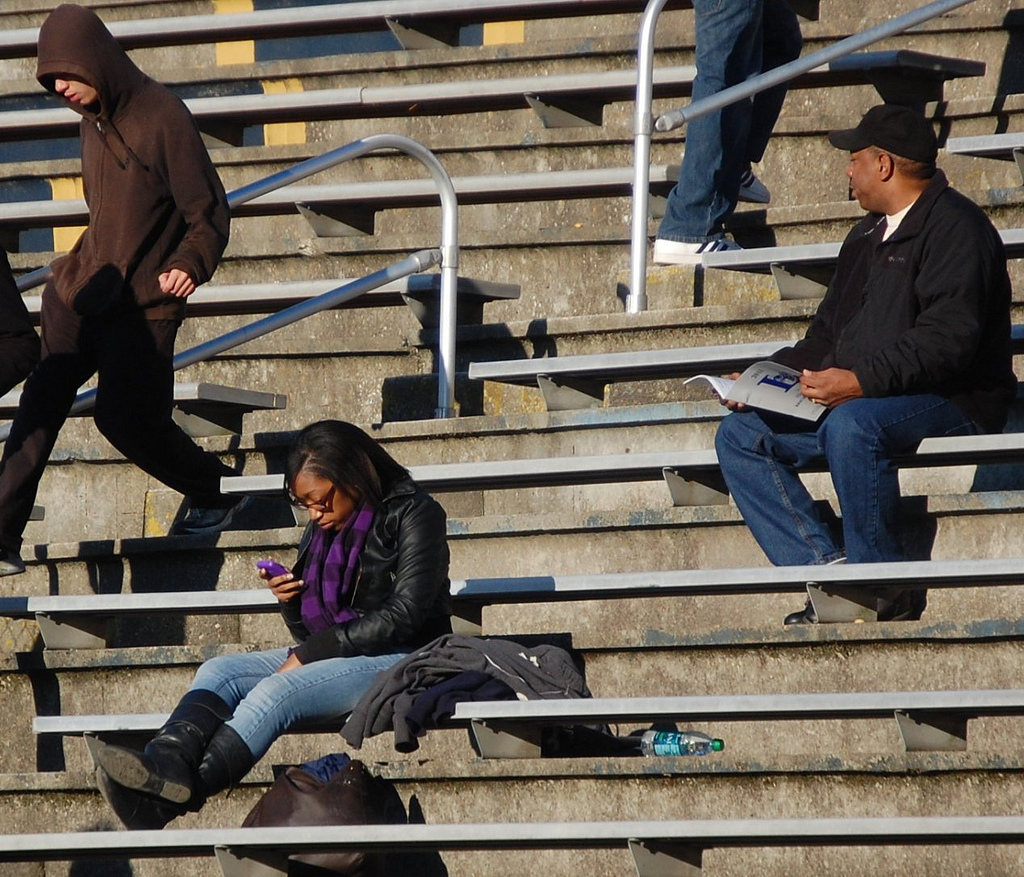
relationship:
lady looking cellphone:
[85, 418, 454, 813] [218, 494, 338, 641]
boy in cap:
[792, 92, 952, 346] [829, 104, 939, 165]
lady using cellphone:
[85, 418, 454, 813] [218, 494, 338, 641]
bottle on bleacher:
[641, 730, 726, 757] [686, 696, 730, 785]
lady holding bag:
[389, 588, 622, 783] [160, 371, 706, 814]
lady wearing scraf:
[85, 418, 454, 813] [278, 510, 351, 630]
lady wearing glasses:
[85, 418, 454, 813] [250, 452, 370, 519]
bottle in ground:
[542, 665, 754, 817] [667, 669, 738, 758]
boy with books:
[715, 103, 1014, 618] [599, 39, 963, 669]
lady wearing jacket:
[6, 14, 251, 368] [10, 103, 264, 294]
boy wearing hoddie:
[792, 92, 952, 346] [809, 184, 985, 371]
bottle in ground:
[542, 665, 754, 817] [611, 649, 649, 698]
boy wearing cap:
[715, 103, 1014, 618] [829, 104, 939, 165]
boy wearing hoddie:
[715, 103, 1014, 618] [809, 184, 985, 371]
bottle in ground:
[641, 730, 726, 757] [611, 649, 649, 698]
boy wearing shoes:
[715, 103, 1014, 618] [645, 189, 759, 281]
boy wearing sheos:
[715, 103, 1014, 618] [645, 189, 759, 281]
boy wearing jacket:
[715, 103, 1014, 618] [10, 103, 264, 294]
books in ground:
[599, 39, 963, 669] [611, 649, 649, 698]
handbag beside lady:
[389, 588, 622, 783] [85, 418, 454, 813]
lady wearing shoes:
[389, 588, 622, 783] [645, 189, 759, 281]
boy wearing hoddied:
[792, 92, 952, 346] [809, 184, 985, 371]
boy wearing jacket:
[792, 92, 952, 346] [10, 103, 264, 294]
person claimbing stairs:
[637, 77, 746, 305] [632, 80, 823, 207]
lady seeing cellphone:
[85, 418, 454, 813] [218, 494, 338, 641]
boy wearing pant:
[715, 103, 1014, 618] [632, 80, 823, 207]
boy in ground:
[715, 103, 1014, 618] [611, 649, 649, 698]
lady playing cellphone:
[85, 418, 454, 813] [218, 494, 338, 641]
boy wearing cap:
[715, 103, 1014, 618] [792, 107, 946, 174]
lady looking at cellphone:
[85, 418, 454, 813] [218, 494, 338, 641]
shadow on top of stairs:
[451, 305, 596, 419] [505, 50, 607, 142]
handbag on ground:
[409, 620, 593, 746] [611, 649, 649, 698]